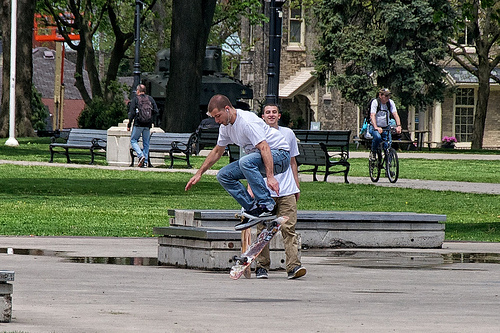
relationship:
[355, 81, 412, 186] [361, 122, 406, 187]
man riding bicycle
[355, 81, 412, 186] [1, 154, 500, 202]
man on sidewalk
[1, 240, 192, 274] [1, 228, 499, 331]
water on concrete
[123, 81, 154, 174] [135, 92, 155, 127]
man carrying backpack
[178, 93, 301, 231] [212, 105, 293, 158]
skateboarder wears t-shirt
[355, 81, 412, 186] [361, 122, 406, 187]
man driving bicycle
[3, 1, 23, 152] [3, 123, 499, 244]
post in lawn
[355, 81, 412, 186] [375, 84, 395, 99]
man wears cap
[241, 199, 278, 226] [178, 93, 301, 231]
shoes on skateboarder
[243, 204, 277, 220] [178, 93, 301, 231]
shoes on skateboarder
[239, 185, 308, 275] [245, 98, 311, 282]
pants on man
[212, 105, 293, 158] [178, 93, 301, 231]
t-shirt on skateboarder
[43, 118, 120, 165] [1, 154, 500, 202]
bench by sidewalk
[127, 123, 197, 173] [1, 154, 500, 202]
bench by sidewalk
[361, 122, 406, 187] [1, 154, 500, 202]
bicycle on sidewalk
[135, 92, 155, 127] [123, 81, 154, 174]
backpack on man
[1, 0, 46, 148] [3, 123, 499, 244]
tree in lawn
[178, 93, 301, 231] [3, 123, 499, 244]
skateboarder in lawn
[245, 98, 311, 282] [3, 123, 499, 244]
man in lawn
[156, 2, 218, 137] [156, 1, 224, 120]
trunk of tree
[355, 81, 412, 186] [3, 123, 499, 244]
man in lawn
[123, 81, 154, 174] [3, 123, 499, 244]
man in lawn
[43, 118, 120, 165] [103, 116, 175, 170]
bench by pedestal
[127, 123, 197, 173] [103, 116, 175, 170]
bench by pedestal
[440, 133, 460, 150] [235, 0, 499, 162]
pot front building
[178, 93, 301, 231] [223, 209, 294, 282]
skateboarder on skateboard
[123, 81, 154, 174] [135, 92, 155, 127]
man wearing backpack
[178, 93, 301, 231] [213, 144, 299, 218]
skateboarder wearing jeans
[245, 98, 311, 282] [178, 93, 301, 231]
man watches skateboarder